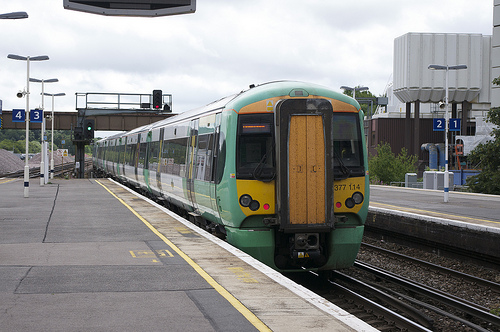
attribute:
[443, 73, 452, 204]
pole — white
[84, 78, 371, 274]
train — long, green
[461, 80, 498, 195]
tree — leafy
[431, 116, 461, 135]
signs — numbered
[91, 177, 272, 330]
stripe — yellow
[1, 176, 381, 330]
platform — concrete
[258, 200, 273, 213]
light — red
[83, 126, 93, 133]
light — green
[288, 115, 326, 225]
door — yellow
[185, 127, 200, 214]
door — closed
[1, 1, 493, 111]
cloud — white